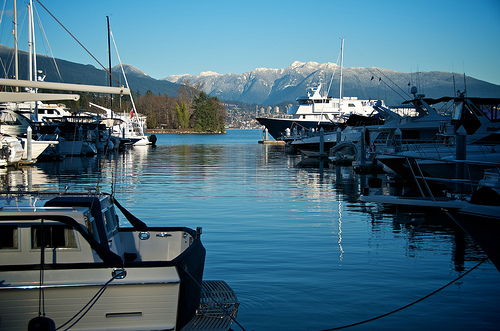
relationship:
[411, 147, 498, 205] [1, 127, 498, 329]
boat in water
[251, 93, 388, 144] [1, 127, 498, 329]
boat in water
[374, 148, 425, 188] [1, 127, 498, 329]
boat in water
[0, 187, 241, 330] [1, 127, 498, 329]
boat in water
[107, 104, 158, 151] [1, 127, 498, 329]
boat in water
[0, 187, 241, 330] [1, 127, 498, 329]
boat on water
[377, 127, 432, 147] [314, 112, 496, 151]
window on boat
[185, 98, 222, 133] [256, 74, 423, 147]
trees growing beyond boats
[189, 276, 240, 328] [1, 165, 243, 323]
deck on boat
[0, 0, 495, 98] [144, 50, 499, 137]
sky above mountains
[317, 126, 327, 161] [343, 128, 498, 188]
posts on dock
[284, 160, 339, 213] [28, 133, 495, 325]
reflection on water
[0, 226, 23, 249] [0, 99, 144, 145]
window on boat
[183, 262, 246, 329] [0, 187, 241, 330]
rope from boat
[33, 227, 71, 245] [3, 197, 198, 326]
window on boat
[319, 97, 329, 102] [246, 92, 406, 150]
window on boat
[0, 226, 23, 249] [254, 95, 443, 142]
window on boat